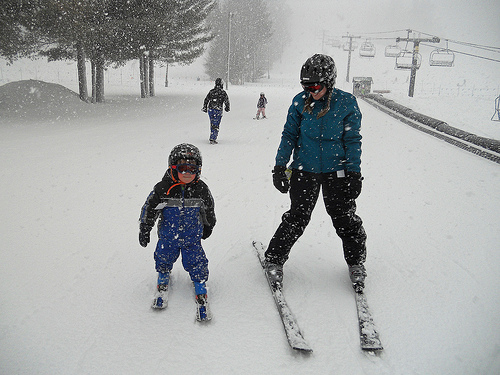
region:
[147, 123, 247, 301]
little person trying to ski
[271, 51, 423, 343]
lady watching little boy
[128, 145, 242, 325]
the blue and black snow suit of little boy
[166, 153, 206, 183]
googles to protect little boys eyes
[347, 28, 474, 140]
ski lift to carry skiers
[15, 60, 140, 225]
snow falling from the sky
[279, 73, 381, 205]
lady wearing a green snow jacket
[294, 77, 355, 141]
long blond hair on lady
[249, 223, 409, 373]
skis and boots of lady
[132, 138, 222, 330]
Child ejoying winter outdoors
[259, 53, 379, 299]
Athletic person talking to child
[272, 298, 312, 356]
Ski for athletic person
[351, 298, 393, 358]
Ski for athletic person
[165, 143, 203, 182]
Head of child on ski slope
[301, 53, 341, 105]
Head of adult on ski slope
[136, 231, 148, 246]
Gloved hand on hand of child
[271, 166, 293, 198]
Gloved hand on adult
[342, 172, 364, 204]
gloved hand on adult's hand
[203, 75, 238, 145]
adult person on ski slope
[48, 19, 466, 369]
It is snowing hard.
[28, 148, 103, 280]
The snow is white.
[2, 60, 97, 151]
The snow has drifts.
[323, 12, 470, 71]
The ski lift is moving.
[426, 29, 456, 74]
The ski car is empty.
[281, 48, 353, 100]
The woman is wearing a black helmet.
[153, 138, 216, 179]
The child is wearing a black helmet.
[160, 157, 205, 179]
The child is wearing goggles.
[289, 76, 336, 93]
The woman is wearing goggles.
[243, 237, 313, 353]
The ski is snow covered.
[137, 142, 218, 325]
A child in a ski suit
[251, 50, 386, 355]
A woman on skis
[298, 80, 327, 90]
A pair of ski goggles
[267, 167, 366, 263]
A pair of black ski pants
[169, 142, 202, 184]
A black ski helmet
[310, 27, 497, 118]
A ski chair lift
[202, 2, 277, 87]
An evergreen tree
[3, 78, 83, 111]
A snow pile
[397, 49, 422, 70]
A lift chair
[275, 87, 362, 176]
A teal ski jacket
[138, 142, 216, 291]
Boy wearing a snowsuit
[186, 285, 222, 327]
Ski on the boy's foot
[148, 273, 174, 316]
Ski on the boy's foot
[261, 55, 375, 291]
Woman wearing black pants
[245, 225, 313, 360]
Ski on the woman's foot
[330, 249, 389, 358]
Ski on the woman's foot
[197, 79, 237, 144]
Person walking in the background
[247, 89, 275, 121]
Child walking on the snow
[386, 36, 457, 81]
Ski lifts in the background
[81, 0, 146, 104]
tree is tall and green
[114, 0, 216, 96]
tree is tall and green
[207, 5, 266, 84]
tree is tall and green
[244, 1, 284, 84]
tree is tall and green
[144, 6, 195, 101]
tree is tall and green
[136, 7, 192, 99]
tree is tall and green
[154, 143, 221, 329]
A little person in the snow.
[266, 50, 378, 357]
A person on top of skis.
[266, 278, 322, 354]
Snow on the ski.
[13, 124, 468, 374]
The ground is covered in snow.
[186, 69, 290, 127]
People playing int he snow.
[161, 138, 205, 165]
The little person is wearing a cap